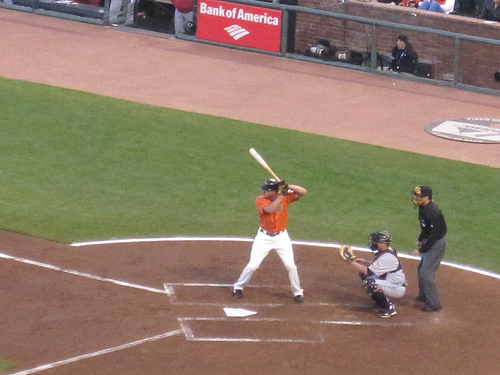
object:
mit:
[336, 242, 358, 267]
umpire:
[404, 183, 446, 315]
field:
[124, 139, 226, 215]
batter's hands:
[277, 176, 290, 195]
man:
[219, 169, 335, 324]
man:
[350, 209, 407, 319]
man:
[408, 184, 451, 317]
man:
[225, 140, 322, 306]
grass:
[455, 178, 499, 253]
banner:
[191, 0, 283, 54]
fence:
[285, 0, 497, 97]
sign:
[425, 117, 498, 143]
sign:
[196, 0, 279, 55]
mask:
[410, 184, 434, 211]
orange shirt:
[250, 190, 305, 232]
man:
[225, 167, 308, 302]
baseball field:
[0, 73, 499, 375]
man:
[230, 175, 307, 306]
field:
[350, 317, 498, 373]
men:
[212, 132, 459, 331]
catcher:
[334, 226, 414, 324]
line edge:
[68, 234, 136, 251]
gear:
[329, 235, 360, 266]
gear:
[364, 227, 398, 253]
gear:
[367, 286, 401, 321]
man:
[205, 151, 326, 304]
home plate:
[215, 302, 264, 321]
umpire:
[411, 183, 449, 313]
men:
[230, 176, 446, 318]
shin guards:
[367, 285, 394, 315]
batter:
[232, 175, 313, 299]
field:
[28, 119, 171, 211]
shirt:
[409, 203, 455, 257]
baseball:
[125, 41, 490, 364]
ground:
[3, 280, 189, 373]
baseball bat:
[242, 146, 293, 196]